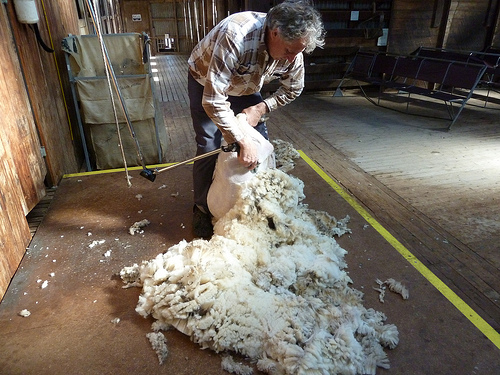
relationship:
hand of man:
[246, 105, 273, 127] [211, 3, 309, 153]